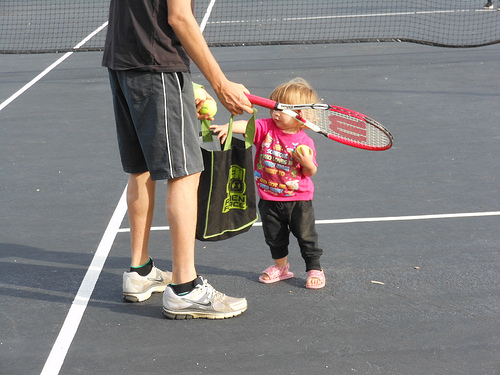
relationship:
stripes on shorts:
[158, 67, 189, 179] [98, 50, 214, 191]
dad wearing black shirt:
[101, 0, 253, 320] [102, 0, 190, 73]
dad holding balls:
[101, 0, 253, 320] [191, 79, 221, 126]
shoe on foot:
[160, 275, 247, 323] [160, 277, 247, 324]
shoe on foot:
[120, 267, 175, 302] [122, 265, 169, 302]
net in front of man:
[0, 0, 500, 55] [68, 7, 260, 347]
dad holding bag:
[101, 0, 253, 320] [195, 107, 260, 239]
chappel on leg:
[247, 257, 332, 297] [260, 209, 292, 264]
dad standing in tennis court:
[101, 0, 253, 320] [287, 30, 494, 245]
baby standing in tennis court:
[210, 83, 326, 289] [287, 30, 494, 245]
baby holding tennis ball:
[210, 83, 326, 289] [199, 94, 219, 120]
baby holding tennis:
[210, 83, 326, 289] [294, 145, 313, 158]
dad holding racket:
[101, 0, 253, 320] [244, 92, 394, 151]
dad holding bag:
[101, 0, 253, 320] [193, 115, 272, 254]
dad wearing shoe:
[101, 0, 253, 320] [162, 275, 248, 319]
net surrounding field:
[225, 2, 490, 39] [299, 42, 498, 354]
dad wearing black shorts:
[101, 0, 253, 320] [104, 65, 209, 190]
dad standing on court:
[101, 0, 253, 320] [0, 0, 500, 375]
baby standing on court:
[210, 83, 326, 289] [0, 0, 500, 375]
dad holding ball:
[101, 0, 253, 320] [185, 89, 222, 130]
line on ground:
[319, 205, 490, 230] [6, 5, 496, 371]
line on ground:
[32, 225, 138, 355] [6, 5, 496, 371]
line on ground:
[7, 53, 84, 111] [6, 5, 496, 371]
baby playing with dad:
[210, 83, 326, 289] [104, 0, 250, 317]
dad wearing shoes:
[101, 0, 253, 320] [124, 254, 262, 349]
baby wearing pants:
[210, 83, 326, 289] [259, 201, 321, 271]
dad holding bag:
[101, 0, 253, 320] [193, 100, 274, 257]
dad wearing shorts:
[101, 0, 253, 320] [108, 63, 204, 178]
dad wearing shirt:
[101, 0, 253, 320] [99, 1, 190, 80]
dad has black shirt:
[101, 0, 253, 320] [100, 3, 177, 71]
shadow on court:
[5, 248, 266, 270] [314, 42, 494, 372]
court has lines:
[394, 31, 476, 246] [88, 210, 190, 278]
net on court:
[0, 0, 500, 55] [399, 55, 499, 365]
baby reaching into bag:
[210, 83, 326, 289] [189, 99, 260, 244]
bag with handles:
[179, 101, 270, 255] [196, 101, 257, 148]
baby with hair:
[210, 83, 326, 289] [278, 79, 316, 128]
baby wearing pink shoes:
[210, 83, 326, 289] [248, 250, 335, 299]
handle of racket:
[250, 88, 271, 111] [241, 83, 403, 187]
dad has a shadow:
[101, 0, 253, 320] [4, 239, 117, 306]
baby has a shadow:
[219, 74, 337, 290] [145, 253, 261, 282]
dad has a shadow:
[101, 0, 253, 320] [0, 239, 307, 321]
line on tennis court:
[116, 210, 500, 233] [4, 0, 497, 373]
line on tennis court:
[38, 0, 214, 375] [4, 0, 497, 373]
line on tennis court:
[0, 20, 110, 111] [4, 0, 497, 373]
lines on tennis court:
[205, 9, 500, 25] [4, 0, 497, 373]